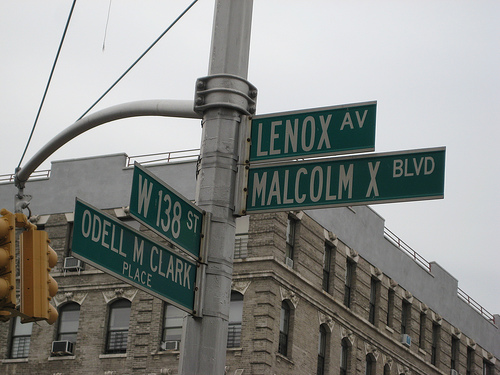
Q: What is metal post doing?
A: Holding street signs.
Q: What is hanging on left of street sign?
A: Yellow stop light.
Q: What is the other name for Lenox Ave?
A: Malcolm X Blvd.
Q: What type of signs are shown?
A: Street signs.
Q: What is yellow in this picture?
A: Traffic light.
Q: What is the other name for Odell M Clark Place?
A: W 138th St.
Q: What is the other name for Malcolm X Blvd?
A: Lenox Ave.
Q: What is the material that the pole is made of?
A: Metal.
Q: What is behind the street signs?
A: A building.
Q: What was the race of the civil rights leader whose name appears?
A: African-American/Black.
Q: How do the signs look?
A: Small and green.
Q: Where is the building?
A: Behind the signs.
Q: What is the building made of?
A: Stone.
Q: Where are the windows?
A: On the building.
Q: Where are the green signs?
A: On the sign post.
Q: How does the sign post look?
A: Tall and grey.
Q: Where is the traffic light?
A: Hanging from the post.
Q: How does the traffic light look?
A: Yellow.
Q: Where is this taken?
A: A city street.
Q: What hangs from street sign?
A: Traffic signal.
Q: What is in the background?
A: Large building.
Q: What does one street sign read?
A: Lenox Avenue.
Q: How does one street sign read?
A: Malcolm X Blvd.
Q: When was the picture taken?
A: Daytime.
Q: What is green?
A: Street signs.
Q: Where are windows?
A: On a building.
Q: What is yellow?
A: Traffic lights.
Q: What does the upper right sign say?
A: "LENOX".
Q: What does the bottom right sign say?
A: "MALCOLM X".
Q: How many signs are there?
A: Four.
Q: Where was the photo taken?
A: At the street corner.